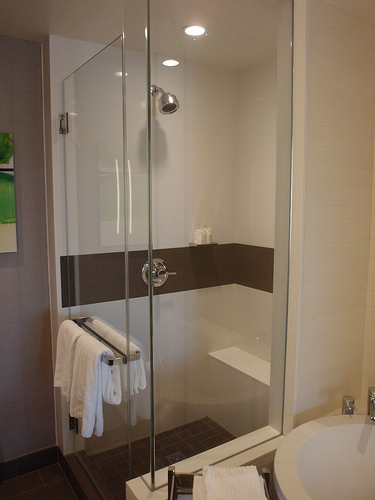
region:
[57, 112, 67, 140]
hinge for shower door.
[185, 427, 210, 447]
tile inside of shower.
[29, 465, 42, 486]
tile on bathroom floor.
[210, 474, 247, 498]
towel near the sink.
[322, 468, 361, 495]
basin of the sink.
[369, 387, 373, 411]
faucet for the sink.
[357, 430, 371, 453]
shadow on the sink.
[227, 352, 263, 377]
seat in the shower.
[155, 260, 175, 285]
handle in the shower.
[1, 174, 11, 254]
picture on the wall.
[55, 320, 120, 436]
the towels are hanging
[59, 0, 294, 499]
the walls are clear glass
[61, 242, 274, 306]
the bathroom has a brown stripe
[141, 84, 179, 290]
the fixtures are silver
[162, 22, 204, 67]
a light in the shower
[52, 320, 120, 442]
the towels are white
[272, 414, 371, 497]
the sink is white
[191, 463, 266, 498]
the towels are folded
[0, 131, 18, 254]
a green painting on wall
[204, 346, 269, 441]
a seat in the shower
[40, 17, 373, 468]
a bathroom shower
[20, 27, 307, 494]
a glass bathroom shower door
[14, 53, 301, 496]
a glass shower door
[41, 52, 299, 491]
a clear shower door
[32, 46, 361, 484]
a clear bathroom shower door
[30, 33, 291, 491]
a shwoer with glass doors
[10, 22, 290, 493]
a shower with clear doors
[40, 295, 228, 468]
towels hanging on a door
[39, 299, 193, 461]
white towels hanging on the door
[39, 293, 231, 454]
a shower door with towels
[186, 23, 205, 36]
recessed light in ceiling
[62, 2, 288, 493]
glass enclosure around shower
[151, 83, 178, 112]
metal shower head on wall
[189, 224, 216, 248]
toiletries on wall shelf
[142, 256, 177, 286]
handle on metal base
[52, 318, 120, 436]
two hanging white towels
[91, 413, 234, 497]
tiles on shower floor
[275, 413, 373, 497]
edge of round sink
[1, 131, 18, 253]
edge of hanging art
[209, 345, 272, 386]
white bench on wall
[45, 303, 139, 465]
white towels on towel rack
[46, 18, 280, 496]
shower with clear door and wall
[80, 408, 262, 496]
shower floor made of brown tile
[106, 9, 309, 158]
recessed lighting in shower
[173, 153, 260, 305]
shelf on shower wall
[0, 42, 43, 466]
grey wall with green artwork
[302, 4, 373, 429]
wall lined with white tile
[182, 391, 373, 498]
white towels by sinks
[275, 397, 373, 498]
white sink basin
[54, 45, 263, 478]
shower with white and brown walls